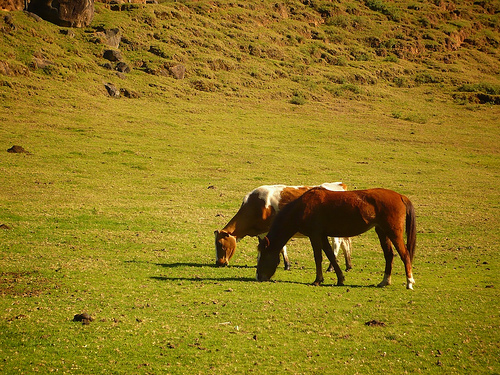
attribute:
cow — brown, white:
[207, 187, 349, 269]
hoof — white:
[384, 259, 479, 334]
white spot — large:
[243, 185, 286, 210]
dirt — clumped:
[74, 312, 93, 325]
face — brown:
[248, 214, 300, 279]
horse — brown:
[219, 159, 451, 311]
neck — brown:
[216, 206, 246, 246]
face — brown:
[210, 223, 235, 284]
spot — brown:
[279, 187, 311, 206]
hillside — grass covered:
[3, 7, 494, 120]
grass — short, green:
[4, 100, 499, 177]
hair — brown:
[402, 194, 417, 266]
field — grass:
[3, 90, 495, 373]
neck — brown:
[268, 197, 301, 247]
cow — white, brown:
[212, 178, 357, 279]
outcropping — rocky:
[0, 1, 499, 93]